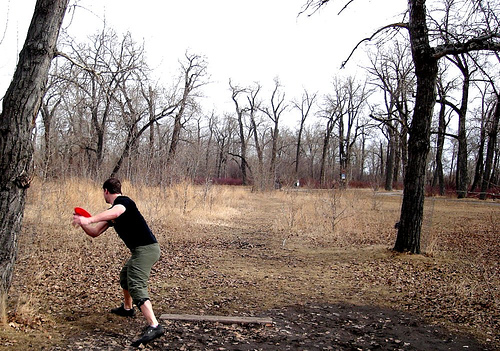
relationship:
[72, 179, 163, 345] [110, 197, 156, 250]
man wearing shirt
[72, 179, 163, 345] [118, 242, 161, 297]
man wearing pants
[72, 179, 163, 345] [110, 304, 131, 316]
man wearing shoe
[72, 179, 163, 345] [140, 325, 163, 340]
man wearing shoe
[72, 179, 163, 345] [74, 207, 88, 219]
man holding frisbee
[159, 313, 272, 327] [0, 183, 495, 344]
plywood on ground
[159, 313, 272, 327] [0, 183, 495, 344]
plywood laying on ground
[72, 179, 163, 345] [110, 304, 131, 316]
man has shoe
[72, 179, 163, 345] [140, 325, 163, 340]
man has shoe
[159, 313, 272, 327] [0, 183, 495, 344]
plywood on top of ground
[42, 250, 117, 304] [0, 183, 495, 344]
leaves on ground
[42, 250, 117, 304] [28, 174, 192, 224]
leaves in theg grass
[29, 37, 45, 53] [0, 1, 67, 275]
knot on tree trunk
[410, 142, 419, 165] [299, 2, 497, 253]
bark on tree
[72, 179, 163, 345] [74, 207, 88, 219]
man throwing frisbee